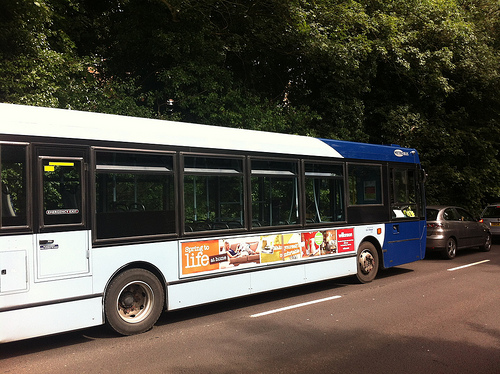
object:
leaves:
[368, 25, 379, 37]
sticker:
[48, 160, 76, 165]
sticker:
[42, 166, 53, 171]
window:
[37, 155, 85, 228]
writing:
[336, 232, 355, 255]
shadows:
[164, 315, 499, 373]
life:
[183, 250, 211, 269]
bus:
[0, 102, 430, 343]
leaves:
[312, 78, 329, 89]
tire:
[102, 265, 165, 335]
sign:
[180, 227, 338, 276]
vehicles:
[425, 202, 492, 260]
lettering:
[199, 254, 211, 269]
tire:
[356, 240, 380, 285]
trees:
[0, 0, 499, 212]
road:
[0, 243, 499, 370]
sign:
[335, 227, 355, 252]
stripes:
[246, 295, 344, 320]